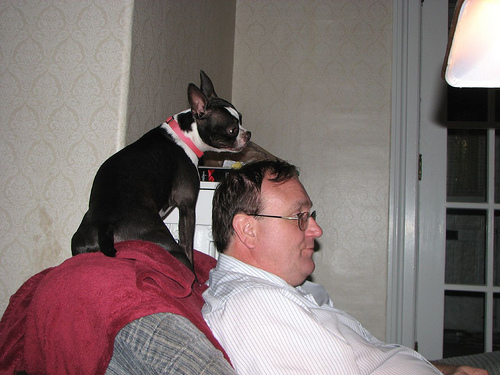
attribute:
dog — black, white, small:
[68, 67, 253, 269]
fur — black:
[68, 72, 255, 251]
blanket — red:
[3, 238, 234, 373]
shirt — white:
[203, 251, 441, 374]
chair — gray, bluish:
[67, 245, 251, 374]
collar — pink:
[157, 114, 202, 161]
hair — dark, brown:
[208, 160, 301, 254]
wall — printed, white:
[1, 2, 391, 336]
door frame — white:
[395, 2, 499, 364]